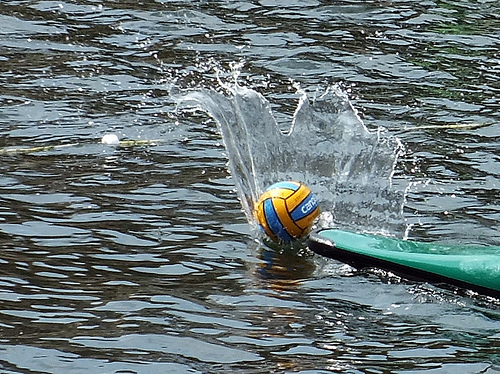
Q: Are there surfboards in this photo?
A: No, there are no surfboards.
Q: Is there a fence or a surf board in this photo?
A: No, there are no surfboards or fences.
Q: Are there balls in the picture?
A: Yes, there is a ball.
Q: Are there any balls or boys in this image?
A: Yes, there is a ball.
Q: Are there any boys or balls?
A: Yes, there is a ball.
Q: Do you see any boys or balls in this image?
A: Yes, there is a ball.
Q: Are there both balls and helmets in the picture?
A: No, there is a ball but no helmets.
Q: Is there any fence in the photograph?
A: No, there are no fences.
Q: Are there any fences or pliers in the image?
A: No, there are no fences or pliers.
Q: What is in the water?
A: The ball is in the water.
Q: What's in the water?
A: The ball is in the water.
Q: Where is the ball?
A: The ball is in the water.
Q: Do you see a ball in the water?
A: Yes, there is a ball in the water.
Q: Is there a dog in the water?
A: No, there is a ball in the water.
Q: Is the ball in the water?
A: Yes, the ball is in the water.